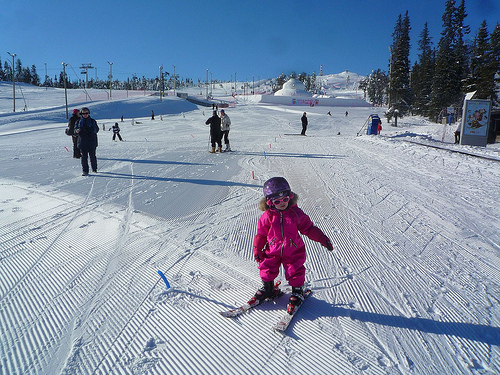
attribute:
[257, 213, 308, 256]
jacket — pink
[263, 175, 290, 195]
helmet — purple, pink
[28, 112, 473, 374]
snow — big, white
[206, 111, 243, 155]
people — standing, in snow track, in snow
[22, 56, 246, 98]
ski lift — in background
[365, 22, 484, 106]
trees — green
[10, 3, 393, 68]
sky — blue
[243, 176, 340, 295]
kid — in pink, on slope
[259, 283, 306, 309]
boots — black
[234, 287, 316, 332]
skis — white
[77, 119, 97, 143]
coat — dark, black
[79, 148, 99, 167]
pants — dark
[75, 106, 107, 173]
person — walking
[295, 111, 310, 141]
person — alone